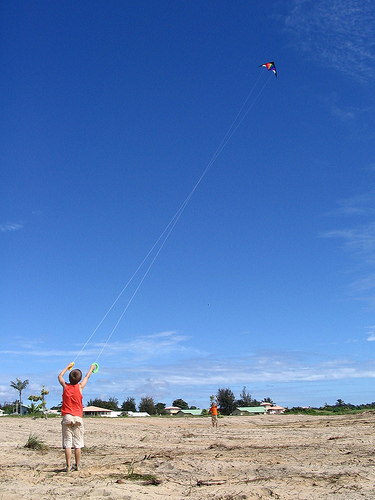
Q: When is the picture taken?
A: Day time.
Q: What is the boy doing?
A: Flying kite.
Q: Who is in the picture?
A: Children.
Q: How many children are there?
A: Two.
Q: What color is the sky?
A: Blue.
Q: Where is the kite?
A: The sky.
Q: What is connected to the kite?
A: String.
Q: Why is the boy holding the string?
A: Control the kite.